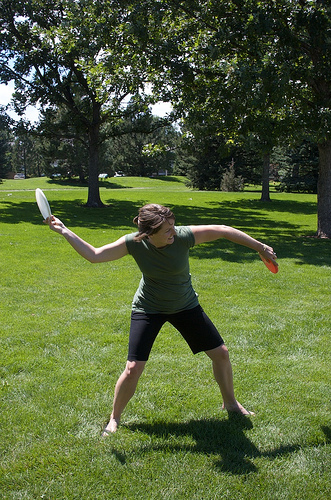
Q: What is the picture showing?
A: It is showing a park.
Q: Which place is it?
A: It is a park.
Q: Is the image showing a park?
A: Yes, it is showing a park.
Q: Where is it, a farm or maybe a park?
A: It is a park.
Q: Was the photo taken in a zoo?
A: No, the picture was taken in a park.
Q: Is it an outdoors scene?
A: Yes, it is outdoors.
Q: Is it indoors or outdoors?
A: It is outdoors.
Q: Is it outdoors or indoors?
A: It is outdoors.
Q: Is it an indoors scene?
A: No, it is outdoors.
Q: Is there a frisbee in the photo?
A: Yes, there is a frisbee.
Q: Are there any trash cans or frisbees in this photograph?
A: Yes, there is a frisbee.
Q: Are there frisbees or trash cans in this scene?
A: Yes, there is a frisbee.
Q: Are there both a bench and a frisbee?
A: No, there is a frisbee but no benches.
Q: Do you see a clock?
A: No, there are no clocks.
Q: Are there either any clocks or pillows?
A: No, there are no clocks or pillows.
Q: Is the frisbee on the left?
A: Yes, the frisbee is on the left of the image.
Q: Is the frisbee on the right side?
A: No, the frisbee is on the left of the image.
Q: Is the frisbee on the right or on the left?
A: The frisbee is on the left of the image.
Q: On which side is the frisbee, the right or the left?
A: The frisbee is on the left of the image.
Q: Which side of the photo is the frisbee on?
A: The frisbee is on the left of the image.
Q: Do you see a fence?
A: No, there are no fences.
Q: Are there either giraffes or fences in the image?
A: No, there are no fences or giraffes.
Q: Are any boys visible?
A: No, there are no boys.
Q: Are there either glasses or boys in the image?
A: No, there are no boys or glasses.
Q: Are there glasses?
A: No, there are no glasses.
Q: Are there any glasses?
A: No, there are no glasses.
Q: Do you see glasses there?
A: No, there are no glasses.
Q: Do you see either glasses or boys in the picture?
A: No, there are no glasses or boys.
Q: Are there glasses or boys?
A: No, there are no glasses or boys.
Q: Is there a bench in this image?
A: No, there are no benches.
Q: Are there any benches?
A: No, there are no benches.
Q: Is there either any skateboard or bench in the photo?
A: No, there are no benches or skateboards.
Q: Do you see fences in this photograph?
A: No, there are no fences.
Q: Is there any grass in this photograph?
A: Yes, there is grass.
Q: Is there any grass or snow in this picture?
A: Yes, there is grass.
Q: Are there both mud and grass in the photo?
A: No, there is grass but no mud.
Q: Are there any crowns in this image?
A: No, there are no crowns.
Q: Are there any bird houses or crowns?
A: No, there are no crowns or bird houses.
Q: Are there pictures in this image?
A: No, there are no pictures.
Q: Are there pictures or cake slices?
A: No, there are no pictures or cake slices.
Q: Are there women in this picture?
A: Yes, there is a woman.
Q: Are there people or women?
A: Yes, there is a woman.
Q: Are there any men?
A: No, there are no men.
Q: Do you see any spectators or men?
A: No, there are no men or spectators.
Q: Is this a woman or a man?
A: This is a woman.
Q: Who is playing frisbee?
A: The woman is playing frisbee.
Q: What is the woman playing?
A: The woman is playing frisbee.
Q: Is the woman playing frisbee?
A: Yes, the woman is playing frisbee.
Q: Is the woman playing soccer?
A: No, the woman is playing frisbee.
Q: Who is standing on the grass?
A: The woman is standing on the grass.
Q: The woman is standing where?
A: The woman is standing on the grass.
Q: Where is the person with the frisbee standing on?
A: The woman is standing on the grass.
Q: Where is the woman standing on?
A: The woman is standing on the grass.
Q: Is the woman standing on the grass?
A: Yes, the woman is standing on the grass.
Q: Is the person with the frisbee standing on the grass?
A: Yes, the woman is standing on the grass.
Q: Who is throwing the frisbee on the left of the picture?
A: The woman is throwing the frisbee.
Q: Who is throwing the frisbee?
A: The woman is throwing the frisbee.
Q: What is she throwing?
A: The woman is throwing the frisbee.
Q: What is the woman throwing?
A: The woman is throwing the frisbee.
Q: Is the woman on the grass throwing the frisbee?
A: Yes, the woman is throwing the frisbee.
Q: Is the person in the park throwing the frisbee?
A: Yes, the woman is throwing the frisbee.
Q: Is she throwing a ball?
A: No, the woman is throwing the frisbee.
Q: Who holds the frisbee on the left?
A: The woman holds the frisbee.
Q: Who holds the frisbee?
A: The woman holds the frisbee.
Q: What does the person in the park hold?
A: The woman holds the frisbee.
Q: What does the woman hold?
A: The woman holds the frisbee.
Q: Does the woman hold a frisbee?
A: Yes, the woman holds a frisbee.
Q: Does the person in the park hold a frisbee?
A: Yes, the woman holds a frisbee.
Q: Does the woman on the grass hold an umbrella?
A: No, the woman holds a frisbee.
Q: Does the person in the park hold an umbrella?
A: No, the woman holds a frisbee.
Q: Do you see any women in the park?
A: Yes, there is a woman in the park.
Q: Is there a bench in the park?
A: No, there is a woman in the park.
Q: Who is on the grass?
A: The woman is on the grass.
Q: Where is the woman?
A: The woman is on the grass.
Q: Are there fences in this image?
A: No, there are no fences.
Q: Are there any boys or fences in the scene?
A: No, there are no fences or boys.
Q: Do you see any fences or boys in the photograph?
A: No, there are no fences or boys.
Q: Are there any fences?
A: No, there are no fences.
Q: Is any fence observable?
A: No, there are no fences.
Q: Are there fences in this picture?
A: No, there are no fences.